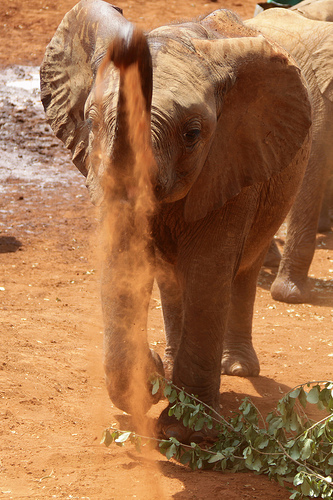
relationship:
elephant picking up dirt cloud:
[41, 0, 313, 439] [93, 66, 162, 479]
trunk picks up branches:
[90, 19, 177, 207] [102, 368, 331, 498]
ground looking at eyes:
[15, 127, 52, 206] [80, 116, 203, 143]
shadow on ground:
[1, 227, 27, 257] [1, 0, 330, 497]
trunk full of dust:
[90, 19, 177, 207] [94, 207, 163, 295]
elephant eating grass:
[41, 0, 313, 439] [153, 375, 202, 422]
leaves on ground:
[83, 372, 332, 496] [3, 181, 131, 498]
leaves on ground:
[83, 372, 332, 496] [258, 303, 331, 389]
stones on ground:
[260, 304, 317, 343] [17, 369, 91, 464]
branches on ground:
[102, 368, 331, 498] [1, 0, 330, 497]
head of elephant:
[108, 39, 318, 164] [69, 37, 285, 335]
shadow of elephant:
[109, 368, 332, 498] [41, 0, 313, 439]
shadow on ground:
[109, 368, 332, 498] [1, 177, 332, 498]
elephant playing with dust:
[41, 0, 313, 439] [90, 24, 153, 459]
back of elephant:
[147, 15, 265, 105] [43, 23, 330, 467]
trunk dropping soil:
[90, 19, 177, 207] [91, 115, 199, 442]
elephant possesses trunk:
[41, 0, 313, 439] [90, 19, 177, 207]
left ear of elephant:
[185, 35, 310, 224] [25, 11, 308, 420]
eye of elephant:
[170, 103, 212, 159] [41, 0, 313, 439]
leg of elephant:
[221, 281, 263, 376] [41, 0, 313, 439]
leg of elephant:
[166, 252, 234, 445] [41, 0, 313, 439]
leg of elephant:
[91, 240, 157, 407] [41, 0, 313, 439]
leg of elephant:
[151, 273, 180, 392] [41, 0, 313, 439]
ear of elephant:
[183, 33, 310, 225] [41, 0, 313, 439]